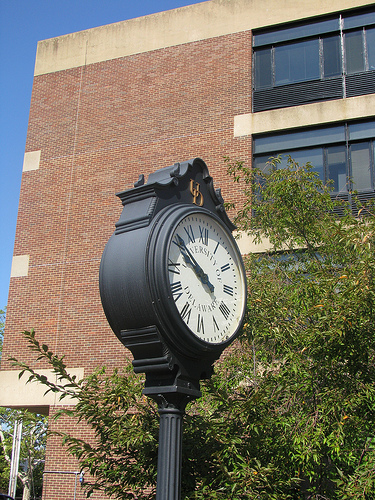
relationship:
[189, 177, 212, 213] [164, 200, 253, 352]
ud on clock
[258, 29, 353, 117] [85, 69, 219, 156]
windows on building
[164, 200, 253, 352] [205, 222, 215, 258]
clock has numerals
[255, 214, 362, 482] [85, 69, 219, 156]
trees near building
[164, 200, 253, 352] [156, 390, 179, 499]
clock on pole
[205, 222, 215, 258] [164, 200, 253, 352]
numerals on clock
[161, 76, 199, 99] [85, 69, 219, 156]
bricks on building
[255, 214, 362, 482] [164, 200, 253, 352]
trees near clock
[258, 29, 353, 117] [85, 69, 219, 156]
windows in building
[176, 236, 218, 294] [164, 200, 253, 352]
hands on clock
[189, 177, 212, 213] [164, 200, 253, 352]
letters on clock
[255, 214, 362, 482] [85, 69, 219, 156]
trees by building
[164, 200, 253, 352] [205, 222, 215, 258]
clock with numerals